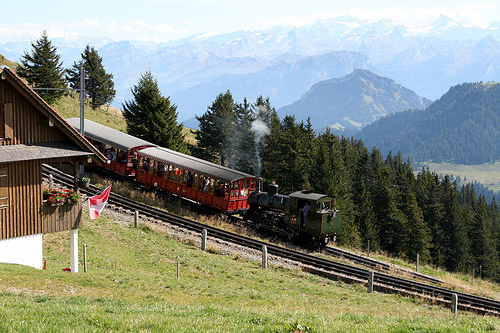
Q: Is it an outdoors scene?
A: Yes, it is outdoors.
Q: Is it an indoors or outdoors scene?
A: It is outdoors.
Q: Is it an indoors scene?
A: No, it is outdoors.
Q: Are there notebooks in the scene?
A: No, there are no notebooks.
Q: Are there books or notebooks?
A: No, there are no notebooks or books.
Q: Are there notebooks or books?
A: No, there are no notebooks or books.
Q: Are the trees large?
A: Yes, the trees are large.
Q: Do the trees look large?
A: Yes, the trees are large.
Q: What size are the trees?
A: The trees are large.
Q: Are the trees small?
A: No, the trees are large.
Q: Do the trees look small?
A: No, the trees are large.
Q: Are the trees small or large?
A: The trees are large.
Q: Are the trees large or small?
A: The trees are large.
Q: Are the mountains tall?
A: Yes, the mountains are tall.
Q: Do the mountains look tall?
A: Yes, the mountains are tall.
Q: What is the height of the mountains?
A: The mountains are tall.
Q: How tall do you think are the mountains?
A: The mountains are tall.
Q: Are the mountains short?
A: No, the mountains are tall.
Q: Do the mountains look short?
A: No, the mountains are tall.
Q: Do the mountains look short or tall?
A: The mountains are tall.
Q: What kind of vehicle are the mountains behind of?
A: The mountains are behind the train.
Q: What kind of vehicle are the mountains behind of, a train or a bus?
A: The mountains are behind a train.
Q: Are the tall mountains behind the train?
A: Yes, the mountains are behind the train.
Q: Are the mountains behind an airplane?
A: No, the mountains are behind the train.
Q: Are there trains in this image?
A: Yes, there is a train.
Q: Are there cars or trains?
A: Yes, there is a train.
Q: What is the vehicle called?
A: The vehicle is a train.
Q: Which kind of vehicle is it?
A: The vehicle is a train.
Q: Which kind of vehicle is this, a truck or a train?
A: This is a train.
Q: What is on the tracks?
A: The train is on the tracks.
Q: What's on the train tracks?
A: The train is on the tracks.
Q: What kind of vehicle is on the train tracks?
A: The vehicle is a train.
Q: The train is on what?
A: The train is on the train tracks.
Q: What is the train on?
A: The train is on the train tracks.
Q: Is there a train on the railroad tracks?
A: Yes, there is a train on the railroad tracks.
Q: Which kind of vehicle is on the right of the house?
A: The vehicle is a train.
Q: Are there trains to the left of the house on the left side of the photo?
A: No, the train is to the right of the house.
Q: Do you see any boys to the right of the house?
A: No, there is a train to the right of the house.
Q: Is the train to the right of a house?
A: Yes, the train is to the right of a house.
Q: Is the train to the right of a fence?
A: No, the train is to the right of a house.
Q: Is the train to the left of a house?
A: No, the train is to the right of a house.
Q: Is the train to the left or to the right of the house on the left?
A: The train is to the right of the house.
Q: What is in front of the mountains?
A: The train is in front of the mountains.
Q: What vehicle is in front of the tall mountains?
A: The vehicle is a train.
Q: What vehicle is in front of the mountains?
A: The vehicle is a train.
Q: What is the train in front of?
A: The train is in front of the mountains.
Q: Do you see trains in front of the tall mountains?
A: Yes, there is a train in front of the mountains.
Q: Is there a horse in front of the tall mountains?
A: No, there is a train in front of the mountains.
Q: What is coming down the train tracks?
A: The train is coming down the railroad tracks.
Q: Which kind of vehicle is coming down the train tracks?
A: The vehicle is a train.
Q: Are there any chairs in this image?
A: No, there are no chairs.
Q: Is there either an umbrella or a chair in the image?
A: No, there are no chairs or umbrellas.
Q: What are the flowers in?
A: The flowers are in the window.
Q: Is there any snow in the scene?
A: Yes, there is snow.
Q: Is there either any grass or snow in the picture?
A: Yes, there is snow.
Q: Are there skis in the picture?
A: No, there are no skis.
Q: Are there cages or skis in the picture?
A: No, there are no skis or cages.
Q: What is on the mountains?
A: The snow is on the mountains.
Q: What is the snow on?
A: The snow is on the mountains.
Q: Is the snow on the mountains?
A: Yes, the snow is on the mountains.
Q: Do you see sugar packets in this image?
A: No, there are no sugar packets.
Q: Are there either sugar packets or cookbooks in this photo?
A: No, there are no sugar packets or cookbooks.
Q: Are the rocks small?
A: Yes, the rocks are small.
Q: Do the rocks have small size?
A: Yes, the rocks are small.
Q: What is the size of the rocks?
A: The rocks are small.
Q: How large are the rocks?
A: The rocks are small.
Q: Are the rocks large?
A: No, the rocks are small.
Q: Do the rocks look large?
A: No, the rocks are small.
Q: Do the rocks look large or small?
A: The rocks are small.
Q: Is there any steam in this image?
A: Yes, there is steam.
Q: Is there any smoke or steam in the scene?
A: Yes, there is steam.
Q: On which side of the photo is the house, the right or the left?
A: The house is on the left of the image.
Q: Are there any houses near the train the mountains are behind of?
A: Yes, there is a house near the train.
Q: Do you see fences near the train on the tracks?
A: No, there is a house near the train.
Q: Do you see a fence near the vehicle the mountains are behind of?
A: No, there is a house near the train.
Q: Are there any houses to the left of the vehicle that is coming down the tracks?
A: Yes, there is a house to the left of the train.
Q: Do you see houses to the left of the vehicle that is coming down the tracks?
A: Yes, there is a house to the left of the train.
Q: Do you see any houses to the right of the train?
A: No, the house is to the left of the train.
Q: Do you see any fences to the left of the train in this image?
A: No, there is a house to the left of the train.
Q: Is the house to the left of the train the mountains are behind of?
A: Yes, the house is to the left of the train.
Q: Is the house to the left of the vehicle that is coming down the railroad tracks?
A: Yes, the house is to the left of the train.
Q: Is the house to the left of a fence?
A: No, the house is to the left of the train.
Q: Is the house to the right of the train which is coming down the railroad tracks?
A: No, the house is to the left of the train.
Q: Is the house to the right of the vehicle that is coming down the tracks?
A: No, the house is to the left of the train.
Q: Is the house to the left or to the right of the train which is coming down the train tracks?
A: The house is to the left of the train.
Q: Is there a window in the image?
A: Yes, there is a window.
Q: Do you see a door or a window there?
A: Yes, there is a window.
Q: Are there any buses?
A: No, there are no buses.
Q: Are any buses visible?
A: No, there are no buses.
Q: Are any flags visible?
A: Yes, there is a flag.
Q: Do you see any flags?
A: Yes, there is a flag.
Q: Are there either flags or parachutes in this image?
A: Yes, there is a flag.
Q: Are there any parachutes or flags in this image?
A: Yes, there is a flag.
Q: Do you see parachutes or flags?
A: Yes, there is a flag.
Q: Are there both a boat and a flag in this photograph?
A: No, there is a flag but no boats.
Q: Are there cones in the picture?
A: No, there are no cones.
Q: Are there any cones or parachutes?
A: No, there are no cones or parachutes.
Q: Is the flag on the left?
A: Yes, the flag is on the left of the image.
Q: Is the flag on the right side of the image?
A: No, the flag is on the left of the image.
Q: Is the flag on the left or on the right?
A: The flag is on the left of the image.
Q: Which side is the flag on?
A: The flag is on the left of the image.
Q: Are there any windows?
A: Yes, there are windows.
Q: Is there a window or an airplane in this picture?
A: Yes, there are windows.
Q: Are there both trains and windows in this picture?
A: Yes, there are both windows and a train.